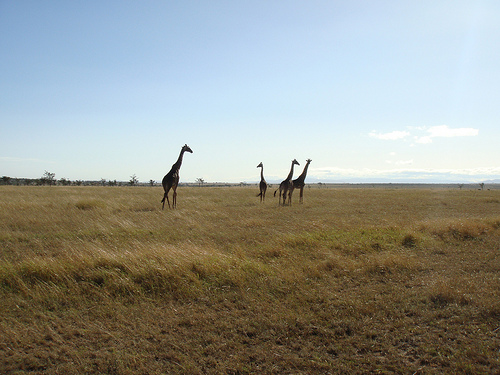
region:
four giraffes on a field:
[122, 125, 355, 243]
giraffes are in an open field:
[129, 131, 334, 216]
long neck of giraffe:
[170, 148, 187, 167]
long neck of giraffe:
[257, 166, 267, 176]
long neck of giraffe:
[299, 160, 313, 176]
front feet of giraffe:
[169, 186, 182, 211]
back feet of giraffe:
[159, 188, 171, 211]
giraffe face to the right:
[154, 138, 200, 210]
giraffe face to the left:
[251, 157, 271, 203]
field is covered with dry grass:
[0, 182, 497, 372]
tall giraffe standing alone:
[155, 140, 194, 210]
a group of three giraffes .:
[253, 156, 314, 203]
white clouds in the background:
[370, 125, 478, 155]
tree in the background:
[41, 168, 55, 185]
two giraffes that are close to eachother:
[274, 155, 312, 208]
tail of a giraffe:
[270, 185, 277, 202]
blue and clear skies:
[1, 0, 351, 142]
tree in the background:
[195, 177, 205, 185]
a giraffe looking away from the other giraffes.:
[255, 162, 269, 202]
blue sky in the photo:
[54, 17, 156, 90]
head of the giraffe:
[173, 138, 207, 162]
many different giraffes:
[117, 126, 345, 278]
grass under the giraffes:
[160, 197, 257, 261]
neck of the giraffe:
[166, 148, 192, 168]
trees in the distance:
[24, 169, 126, 210]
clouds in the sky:
[368, 80, 474, 161]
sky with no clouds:
[1, 16, 107, 105]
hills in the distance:
[376, 165, 438, 194]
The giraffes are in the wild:
[110, 111, 346, 229]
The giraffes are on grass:
[56, 185, 483, 269]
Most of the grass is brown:
[9, 192, 489, 362]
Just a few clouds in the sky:
[355, 124, 472, 159]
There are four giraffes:
[143, 127, 337, 215]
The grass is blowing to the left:
[27, 230, 198, 297]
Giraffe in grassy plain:
[125, 137, 345, 238]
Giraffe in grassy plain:
[150, 130, 316, 231]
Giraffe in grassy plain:
[153, 135, 318, 225]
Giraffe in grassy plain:
[151, 132, 321, 233]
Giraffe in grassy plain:
[146, 136, 323, 228]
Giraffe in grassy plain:
[147, 127, 322, 237]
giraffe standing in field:
[155, 135, 195, 211]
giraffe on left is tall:
[148, 138, 199, 211]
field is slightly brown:
[2, 181, 499, 374]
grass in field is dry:
[0, 183, 499, 373]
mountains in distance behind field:
[279, 166, 498, 190]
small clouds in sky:
[368, 121, 475, 160]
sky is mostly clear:
[0, 1, 499, 192]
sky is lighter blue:
[1, 0, 496, 187]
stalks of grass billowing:
[11, 213, 247, 298]